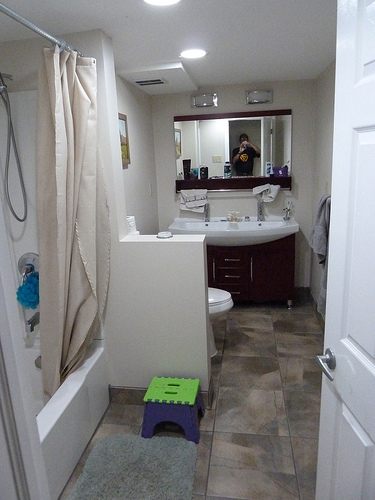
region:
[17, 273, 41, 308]
blue luffa is hanging in the shower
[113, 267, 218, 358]
a wall partition between the shower and toilet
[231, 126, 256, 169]
reflection of a man taking a photo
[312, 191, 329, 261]
a towel hanging on a rack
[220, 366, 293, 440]
tiles on the bathroom floor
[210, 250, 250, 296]
drawers are under the sink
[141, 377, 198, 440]
the step stool is for a child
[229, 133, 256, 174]
The man is wearing a sweater.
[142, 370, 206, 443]
The step stool is purple and green.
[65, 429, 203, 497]
The bathroom rug is green.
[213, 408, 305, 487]
The bathroom floor is made from tile.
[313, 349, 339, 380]
The door handle is silver.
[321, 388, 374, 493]
The door is white.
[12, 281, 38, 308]
The bath sponge is blue.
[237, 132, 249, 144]
The man has brown hair.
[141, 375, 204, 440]
a blue and green step stool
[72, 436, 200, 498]
a blue bathroom mat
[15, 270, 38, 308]
a blue shower scrubber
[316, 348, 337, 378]
silver door handle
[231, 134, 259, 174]
a person's reflection in the mirror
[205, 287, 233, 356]
the toilet is white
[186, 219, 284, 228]
a large oval sink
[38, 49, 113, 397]
a cream colored shower curtain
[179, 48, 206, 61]
round roof lighting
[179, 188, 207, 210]
hand towel hanging on the rack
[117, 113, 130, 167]
Picture frame on a wall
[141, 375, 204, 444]
A step stool on the floor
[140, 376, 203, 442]
A green and blue step stool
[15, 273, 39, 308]
A blue wash cloth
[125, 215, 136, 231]
Roll of toilet paper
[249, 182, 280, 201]
A white towel in a bathroom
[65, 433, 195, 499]
A bathroom floor rug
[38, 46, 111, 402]
A light colored shower curtain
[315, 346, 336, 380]
A metal door handle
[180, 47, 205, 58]
A bright light in a bathroom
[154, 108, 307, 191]
the mirror on the wall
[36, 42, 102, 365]
shower curtain is open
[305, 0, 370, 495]
bathroom door is open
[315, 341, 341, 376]
knob on the door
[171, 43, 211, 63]
light on the ceiling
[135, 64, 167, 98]
vent on the ceiling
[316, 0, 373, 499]
the door is white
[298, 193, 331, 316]
the gray towel is hanging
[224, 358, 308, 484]
floor is tiled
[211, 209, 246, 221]
toiletries on the sink